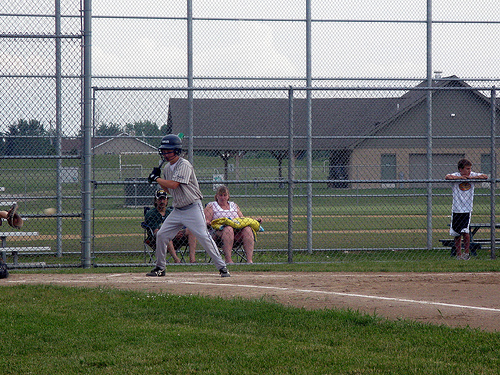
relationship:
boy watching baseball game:
[445, 153, 481, 260] [37, 61, 497, 360]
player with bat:
[154, 133, 228, 280] [157, 164, 165, 169]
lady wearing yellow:
[216, 187, 257, 248] [220, 213, 223, 215]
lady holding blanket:
[216, 187, 257, 248] [230, 218, 256, 228]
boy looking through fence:
[445, 153, 481, 260] [291, 104, 320, 191]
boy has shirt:
[445, 153, 481, 260] [460, 193, 472, 209]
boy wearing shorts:
[445, 153, 481, 260] [452, 214, 472, 229]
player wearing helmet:
[154, 133, 228, 280] [159, 136, 178, 146]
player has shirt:
[154, 133, 228, 280] [168, 173, 199, 200]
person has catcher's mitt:
[2, 210, 3, 218] [12, 207, 22, 227]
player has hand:
[154, 133, 228, 280] [151, 174, 157, 177]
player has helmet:
[154, 133, 228, 280] [159, 136, 178, 146]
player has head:
[154, 133, 228, 280] [170, 151, 179, 154]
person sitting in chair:
[151, 187, 168, 225] [149, 234, 154, 242]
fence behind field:
[291, 104, 320, 191] [101, 289, 449, 371]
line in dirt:
[328, 289, 400, 301] [381, 284, 414, 290]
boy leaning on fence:
[445, 153, 481, 260] [291, 104, 320, 191]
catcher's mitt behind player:
[12, 207, 22, 227] [154, 133, 228, 280]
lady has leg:
[216, 187, 257, 248] [225, 234, 233, 260]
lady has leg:
[216, 187, 257, 248] [244, 233, 257, 258]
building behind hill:
[92, 127, 145, 153] [92, 157, 116, 170]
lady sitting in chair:
[216, 187, 257, 248] [236, 246, 244, 256]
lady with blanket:
[216, 187, 257, 248] [230, 218, 256, 228]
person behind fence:
[151, 187, 168, 225] [291, 104, 320, 191]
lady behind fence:
[216, 187, 257, 248] [291, 104, 320, 191]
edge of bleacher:
[44, 246, 51, 251] [3, 248, 17, 252]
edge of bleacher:
[36, 233, 38, 236] [3, 233, 27, 237]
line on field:
[328, 289, 400, 301] [0, 249, 500, 371]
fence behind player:
[291, 104, 320, 191] [154, 133, 228, 280]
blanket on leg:
[230, 218, 256, 228] [225, 234, 233, 260]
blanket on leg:
[230, 218, 256, 228] [244, 233, 257, 258]